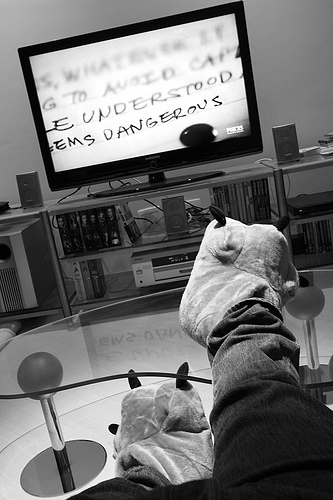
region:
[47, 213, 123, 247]
The movies on the top shelf.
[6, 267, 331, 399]
The glass top of the table.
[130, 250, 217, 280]
The VCR on the bottom of the shelf.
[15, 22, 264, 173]
The flat screen in the room.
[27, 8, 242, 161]
The screen of the t.v.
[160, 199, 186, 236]
The portable speaker on the second shelf.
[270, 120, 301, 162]
The portable speaker on the right.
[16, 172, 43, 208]
The portable speaker on the left.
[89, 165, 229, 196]
The stand of the t.v.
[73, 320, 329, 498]
The jeans the person sitting down is wearing.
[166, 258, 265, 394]
this is a slipper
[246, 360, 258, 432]
this is a pair of jeans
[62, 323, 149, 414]
the photo is black and white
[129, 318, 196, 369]
this is a table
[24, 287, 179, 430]
the table is black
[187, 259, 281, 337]
the slippers are fluffy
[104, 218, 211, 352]
this is a dvd player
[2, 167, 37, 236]
this is a speaker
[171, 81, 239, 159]
this is a tv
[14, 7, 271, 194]
screen of a tv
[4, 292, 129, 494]
a class table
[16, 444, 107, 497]
sand of a glass table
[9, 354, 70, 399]
a ball under the glass table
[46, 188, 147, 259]
set of dvd under table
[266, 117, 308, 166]
a speaker set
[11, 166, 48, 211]
a speaker on a table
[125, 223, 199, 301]
dvd players and bunch of devices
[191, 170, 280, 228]
a series of dvd under tv stand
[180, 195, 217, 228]
cables behind the tv stand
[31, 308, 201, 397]
the table is made of glass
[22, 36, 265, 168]
the tv is on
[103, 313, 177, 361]
tev reflection is on the glass table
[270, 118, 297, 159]
the speaker is right of the tv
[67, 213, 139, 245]
dvds are on the shelf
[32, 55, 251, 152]
dangerous wod is written on the tv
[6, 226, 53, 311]
the speaker is silver in color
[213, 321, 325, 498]
the jeans are grey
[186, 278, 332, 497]
the leg is on the table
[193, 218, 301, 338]
the legs are in the table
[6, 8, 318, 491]
black and white photo of a person in a room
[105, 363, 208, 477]
furry animal slipper with claws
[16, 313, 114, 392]
glass table set on the floor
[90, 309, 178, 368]
reflection of words in the glass of the table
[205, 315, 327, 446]
person's leg in jeans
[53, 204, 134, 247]
VHS movie tapes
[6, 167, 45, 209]
small speaker set on a table top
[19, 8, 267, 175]
wide-screen television set on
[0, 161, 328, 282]
metal frame shelves with various electronics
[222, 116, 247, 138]
identifying image of broadcasting station